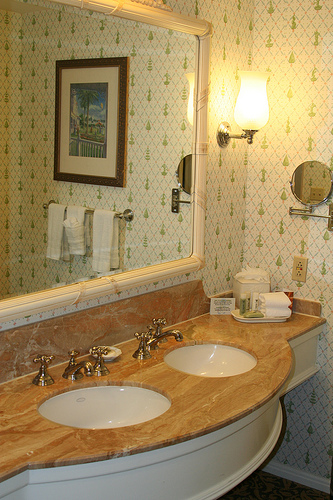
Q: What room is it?
A: It is a bathroom.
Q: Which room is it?
A: It is a bathroom.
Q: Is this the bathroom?
A: Yes, it is the bathroom.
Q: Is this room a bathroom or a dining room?
A: It is a bathroom.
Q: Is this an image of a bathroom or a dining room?
A: It is showing a bathroom.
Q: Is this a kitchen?
A: No, it is a bathroom.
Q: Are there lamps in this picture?
A: Yes, there is a lamp.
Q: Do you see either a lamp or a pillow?
A: Yes, there is a lamp.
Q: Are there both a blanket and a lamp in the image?
A: No, there is a lamp but no blankets.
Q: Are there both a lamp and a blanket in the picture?
A: No, there is a lamp but no blankets.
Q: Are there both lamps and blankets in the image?
A: No, there is a lamp but no blankets.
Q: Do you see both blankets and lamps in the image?
A: No, there is a lamp but no blankets.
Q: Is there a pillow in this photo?
A: No, there are no pillows.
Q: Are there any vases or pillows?
A: No, there are no pillows or vases.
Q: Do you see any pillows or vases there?
A: No, there are no pillows or vases.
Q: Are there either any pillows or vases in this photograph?
A: No, there are no pillows or vases.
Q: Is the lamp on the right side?
A: Yes, the lamp is on the right of the image.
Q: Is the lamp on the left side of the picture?
A: No, the lamp is on the right of the image.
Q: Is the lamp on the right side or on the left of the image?
A: The lamp is on the right of the image.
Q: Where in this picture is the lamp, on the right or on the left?
A: The lamp is on the right of the image.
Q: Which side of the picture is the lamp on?
A: The lamp is on the right of the image.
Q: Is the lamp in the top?
A: Yes, the lamp is in the top of the image.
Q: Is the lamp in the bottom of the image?
A: No, the lamp is in the top of the image.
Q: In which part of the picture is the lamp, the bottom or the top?
A: The lamp is in the top of the image.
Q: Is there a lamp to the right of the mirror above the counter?
A: Yes, there is a lamp to the right of the mirror.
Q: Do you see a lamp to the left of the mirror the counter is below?
A: No, the lamp is to the right of the mirror.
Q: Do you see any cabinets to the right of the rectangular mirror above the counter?
A: No, there is a lamp to the right of the mirror.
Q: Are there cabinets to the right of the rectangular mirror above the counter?
A: No, there is a lamp to the right of the mirror.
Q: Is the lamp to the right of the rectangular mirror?
A: Yes, the lamp is to the right of the mirror.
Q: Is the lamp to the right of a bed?
A: No, the lamp is to the right of the mirror.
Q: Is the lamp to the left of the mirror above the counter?
A: No, the lamp is to the right of the mirror.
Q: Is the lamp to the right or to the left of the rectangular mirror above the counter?
A: The lamp is to the right of the mirror.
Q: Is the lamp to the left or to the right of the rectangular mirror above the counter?
A: The lamp is to the right of the mirror.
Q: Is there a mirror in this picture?
A: Yes, there is a mirror.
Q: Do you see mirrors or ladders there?
A: Yes, there is a mirror.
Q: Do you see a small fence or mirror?
A: Yes, there is a small mirror.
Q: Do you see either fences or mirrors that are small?
A: Yes, the mirror is small.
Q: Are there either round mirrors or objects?
A: Yes, there is a round mirror.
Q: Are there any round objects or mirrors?
A: Yes, there is a round mirror.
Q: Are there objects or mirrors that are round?
A: Yes, the mirror is round.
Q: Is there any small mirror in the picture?
A: Yes, there is a small mirror.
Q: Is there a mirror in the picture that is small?
A: Yes, there is a mirror that is small.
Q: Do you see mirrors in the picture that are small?
A: Yes, there is a mirror that is small.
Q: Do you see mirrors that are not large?
A: Yes, there is a small mirror.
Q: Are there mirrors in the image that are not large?
A: Yes, there is a small mirror.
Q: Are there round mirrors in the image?
A: Yes, there is a round mirror.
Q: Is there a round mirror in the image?
A: Yes, there is a round mirror.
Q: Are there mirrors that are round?
A: Yes, there is a mirror that is round.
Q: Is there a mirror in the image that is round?
A: Yes, there is a mirror that is round.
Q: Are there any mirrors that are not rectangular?
A: Yes, there is a round mirror.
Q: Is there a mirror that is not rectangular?
A: Yes, there is a round mirror.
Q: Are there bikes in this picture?
A: No, there are no bikes.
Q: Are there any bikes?
A: No, there are no bikes.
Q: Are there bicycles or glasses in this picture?
A: No, there are no bicycles or glasses.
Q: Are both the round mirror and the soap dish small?
A: Yes, both the mirror and the soap dish are small.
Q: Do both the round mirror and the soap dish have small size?
A: Yes, both the mirror and the soap dish are small.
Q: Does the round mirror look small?
A: Yes, the mirror is small.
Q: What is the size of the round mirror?
A: The mirror is small.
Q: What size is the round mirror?
A: The mirror is small.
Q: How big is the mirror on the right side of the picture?
A: The mirror is small.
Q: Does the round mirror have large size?
A: No, the mirror is small.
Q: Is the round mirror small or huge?
A: The mirror is small.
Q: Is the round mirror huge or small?
A: The mirror is small.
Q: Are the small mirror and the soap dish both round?
A: Yes, both the mirror and the soap dish are round.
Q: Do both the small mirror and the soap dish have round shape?
A: Yes, both the mirror and the soap dish are round.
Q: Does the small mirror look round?
A: Yes, the mirror is round.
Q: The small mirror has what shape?
A: The mirror is round.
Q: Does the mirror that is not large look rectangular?
A: No, the mirror is round.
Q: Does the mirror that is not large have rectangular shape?
A: No, the mirror is round.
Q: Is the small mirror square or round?
A: The mirror is round.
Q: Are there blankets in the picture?
A: No, there are no blankets.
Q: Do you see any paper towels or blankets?
A: No, there are no blankets or paper towels.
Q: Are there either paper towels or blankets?
A: No, there are no blankets or paper towels.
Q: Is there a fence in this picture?
A: No, there are no fences.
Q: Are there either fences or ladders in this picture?
A: No, there are no fences or ladders.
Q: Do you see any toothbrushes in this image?
A: No, there are no toothbrushes.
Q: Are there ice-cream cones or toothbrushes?
A: No, there are no toothbrushes or ice-cream cones.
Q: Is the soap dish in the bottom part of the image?
A: Yes, the soap dish is in the bottom of the image.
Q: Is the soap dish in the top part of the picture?
A: No, the soap dish is in the bottom of the image.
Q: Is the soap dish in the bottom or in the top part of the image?
A: The soap dish is in the bottom of the image.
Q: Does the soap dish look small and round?
A: Yes, the soap dish is small and round.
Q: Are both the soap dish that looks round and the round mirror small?
A: Yes, both the soap dish and the mirror are small.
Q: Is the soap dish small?
A: Yes, the soap dish is small.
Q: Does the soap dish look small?
A: Yes, the soap dish is small.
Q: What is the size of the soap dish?
A: The soap dish is small.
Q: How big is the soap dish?
A: The soap dish is small.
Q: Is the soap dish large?
A: No, the soap dish is small.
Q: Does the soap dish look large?
A: No, the soap dish is small.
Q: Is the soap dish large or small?
A: The soap dish is small.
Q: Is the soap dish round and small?
A: Yes, the soap dish is round and small.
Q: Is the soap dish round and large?
A: No, the soap dish is round but small.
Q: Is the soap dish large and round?
A: No, the soap dish is round but small.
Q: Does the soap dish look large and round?
A: No, the soap dish is round but small.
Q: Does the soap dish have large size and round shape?
A: No, the soap dish is round but small.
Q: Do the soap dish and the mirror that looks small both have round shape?
A: Yes, both the soap dish and the mirror are round.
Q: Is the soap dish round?
A: Yes, the soap dish is round.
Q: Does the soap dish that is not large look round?
A: Yes, the soap dish is round.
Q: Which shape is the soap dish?
A: The soap dish is round.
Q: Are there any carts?
A: No, there are no carts.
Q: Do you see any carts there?
A: No, there are no carts.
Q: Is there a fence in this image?
A: No, there are no fences.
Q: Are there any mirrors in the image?
A: Yes, there is a mirror.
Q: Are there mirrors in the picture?
A: Yes, there is a mirror.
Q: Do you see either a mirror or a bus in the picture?
A: Yes, there is a mirror.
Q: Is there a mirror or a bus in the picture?
A: Yes, there is a mirror.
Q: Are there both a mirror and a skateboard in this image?
A: No, there is a mirror but no skateboards.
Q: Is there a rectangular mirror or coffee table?
A: Yes, there is a rectangular mirror.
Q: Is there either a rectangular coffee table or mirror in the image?
A: Yes, there is a rectangular mirror.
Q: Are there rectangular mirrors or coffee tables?
A: Yes, there is a rectangular mirror.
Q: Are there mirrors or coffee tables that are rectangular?
A: Yes, the mirror is rectangular.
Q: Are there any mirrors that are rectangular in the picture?
A: Yes, there is a rectangular mirror.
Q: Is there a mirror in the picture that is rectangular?
A: Yes, there is a mirror that is rectangular.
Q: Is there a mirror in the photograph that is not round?
A: Yes, there is a rectangular mirror.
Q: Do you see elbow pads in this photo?
A: No, there are no elbow pads.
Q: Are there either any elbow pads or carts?
A: No, there are no elbow pads or carts.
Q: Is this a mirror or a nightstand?
A: This is a mirror.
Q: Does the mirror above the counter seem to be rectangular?
A: Yes, the mirror is rectangular.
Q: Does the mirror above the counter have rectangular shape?
A: Yes, the mirror is rectangular.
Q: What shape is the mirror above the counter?
A: The mirror is rectangular.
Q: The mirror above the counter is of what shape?
A: The mirror is rectangular.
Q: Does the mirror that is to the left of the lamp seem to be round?
A: No, the mirror is rectangular.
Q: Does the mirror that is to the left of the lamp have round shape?
A: No, the mirror is rectangular.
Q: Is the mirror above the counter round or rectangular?
A: The mirror is rectangular.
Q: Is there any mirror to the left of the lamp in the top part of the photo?
A: Yes, there is a mirror to the left of the lamp.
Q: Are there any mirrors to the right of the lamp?
A: No, the mirror is to the left of the lamp.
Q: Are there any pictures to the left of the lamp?
A: No, there is a mirror to the left of the lamp.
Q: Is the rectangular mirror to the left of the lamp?
A: Yes, the mirror is to the left of the lamp.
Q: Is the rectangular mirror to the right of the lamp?
A: No, the mirror is to the left of the lamp.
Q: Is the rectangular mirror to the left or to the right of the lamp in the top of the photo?
A: The mirror is to the left of the lamp.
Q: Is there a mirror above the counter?
A: Yes, there is a mirror above the counter.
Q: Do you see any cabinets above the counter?
A: No, there is a mirror above the counter.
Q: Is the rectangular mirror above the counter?
A: Yes, the mirror is above the counter.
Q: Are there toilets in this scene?
A: No, there are no toilets.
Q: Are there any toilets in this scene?
A: No, there are no toilets.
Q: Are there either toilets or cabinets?
A: No, there are no toilets or cabinets.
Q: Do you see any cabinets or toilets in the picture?
A: No, there are no toilets or cabinets.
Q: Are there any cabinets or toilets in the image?
A: No, there are no toilets or cabinets.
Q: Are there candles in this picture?
A: No, there are no candles.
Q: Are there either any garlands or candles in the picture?
A: No, there are no candles or garlands.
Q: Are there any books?
A: No, there are no books.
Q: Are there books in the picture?
A: No, there are no books.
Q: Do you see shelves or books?
A: No, there are no books or shelves.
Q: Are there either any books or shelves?
A: No, there are no books or shelves.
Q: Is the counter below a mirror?
A: Yes, the counter is below a mirror.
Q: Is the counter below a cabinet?
A: No, the counter is below a mirror.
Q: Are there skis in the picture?
A: No, there are no skis.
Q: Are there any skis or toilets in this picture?
A: No, there are no skis or toilets.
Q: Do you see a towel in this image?
A: Yes, there is a towel.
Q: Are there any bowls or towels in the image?
A: Yes, there is a towel.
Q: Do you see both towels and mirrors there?
A: Yes, there are both a towel and a mirror.